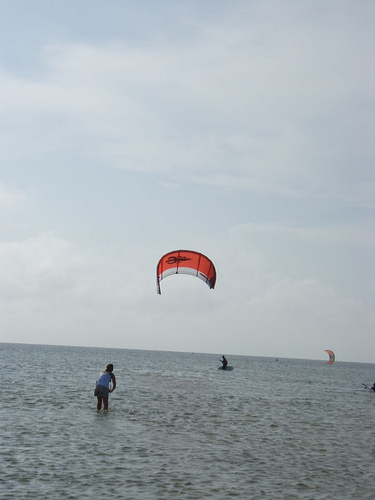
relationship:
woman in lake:
[80, 362, 125, 411] [26, 359, 371, 492]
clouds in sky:
[111, 73, 276, 153] [26, 33, 347, 277]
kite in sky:
[161, 240, 225, 293] [26, 33, 347, 277]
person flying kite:
[215, 342, 238, 385] [161, 240, 225, 293]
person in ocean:
[215, 342, 238, 385] [14, 317, 371, 456]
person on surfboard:
[215, 342, 238, 385] [210, 365, 248, 377]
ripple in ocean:
[78, 434, 276, 468] [14, 317, 371, 456]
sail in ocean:
[321, 349, 341, 378] [14, 317, 371, 456]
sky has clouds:
[26, 33, 347, 277] [111, 73, 276, 153]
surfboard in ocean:
[210, 365, 248, 377] [14, 317, 371, 456]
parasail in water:
[321, 345, 348, 370] [97, 346, 357, 385]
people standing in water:
[59, 336, 249, 430] [97, 346, 357, 385]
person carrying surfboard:
[215, 342, 238, 385] [210, 365, 248, 377]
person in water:
[266, 355, 297, 371] [97, 346, 357, 385]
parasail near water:
[321, 345, 348, 370] [97, 346, 357, 385]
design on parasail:
[168, 253, 200, 272] [146, 244, 229, 296]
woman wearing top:
[80, 362, 125, 411] [98, 372, 112, 388]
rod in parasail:
[173, 246, 186, 280] [146, 244, 229, 296]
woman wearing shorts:
[80, 362, 125, 411] [88, 387, 112, 400]